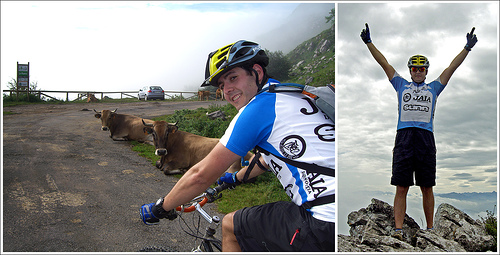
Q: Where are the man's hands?
A: Above head.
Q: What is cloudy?
A: Sky.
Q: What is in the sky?
A: Clouds.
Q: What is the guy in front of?
A: Clouds.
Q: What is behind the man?
A: Sky.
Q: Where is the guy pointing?
A: To the sky.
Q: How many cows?
A: 2.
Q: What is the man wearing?
A: A helmet.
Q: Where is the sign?
A: Behind the fence.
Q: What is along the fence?
A: A car.